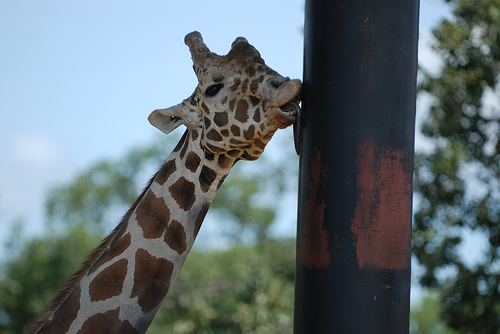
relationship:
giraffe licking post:
[21, 30, 305, 334] [294, 35, 419, 331]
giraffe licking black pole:
[79, 57, 293, 291] [291, 0, 420, 333]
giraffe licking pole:
[21, 30, 305, 334] [294, 3, 419, 330]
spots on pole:
[301, 138, 416, 281] [294, 3, 419, 330]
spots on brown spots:
[301, 138, 416, 281] [132, 248, 173, 312]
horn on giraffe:
[184, 25, 212, 73] [21, 30, 305, 334]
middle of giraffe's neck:
[118, 220, 177, 258] [22, 128, 230, 332]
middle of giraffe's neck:
[118, 220, 177, 258] [22, 130, 249, 331]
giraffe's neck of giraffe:
[22, 130, 249, 331] [2, 3, 314, 330]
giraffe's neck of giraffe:
[22, 130, 249, 331] [93, 170, 230, 297]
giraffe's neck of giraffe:
[22, 130, 249, 331] [91, 50, 288, 331]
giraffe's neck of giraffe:
[22, 130, 249, 331] [21, 30, 305, 334]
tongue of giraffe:
[282, 101, 305, 159] [38, 27, 331, 316]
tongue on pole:
[282, 101, 305, 159] [271, 0, 426, 320]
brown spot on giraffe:
[152, 191, 192, 248] [21, 30, 305, 334]